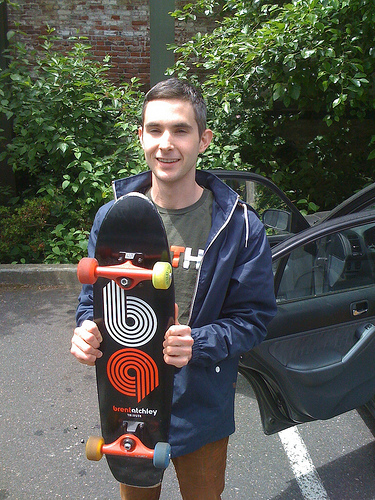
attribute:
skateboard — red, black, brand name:
[47, 192, 202, 464]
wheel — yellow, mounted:
[70, 254, 106, 288]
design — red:
[88, 286, 150, 401]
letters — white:
[188, 248, 204, 270]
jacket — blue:
[176, 225, 289, 460]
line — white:
[279, 436, 319, 479]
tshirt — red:
[148, 200, 229, 325]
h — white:
[180, 237, 212, 275]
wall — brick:
[95, 8, 142, 68]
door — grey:
[310, 238, 373, 379]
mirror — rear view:
[260, 199, 287, 237]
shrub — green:
[205, 19, 314, 144]